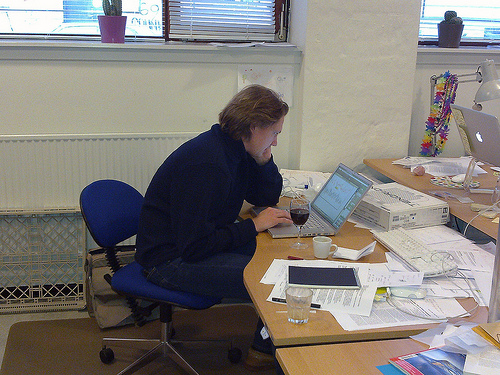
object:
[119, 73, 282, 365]
man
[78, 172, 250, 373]
chair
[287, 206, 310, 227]
wine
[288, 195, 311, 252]
glass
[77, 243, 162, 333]
bag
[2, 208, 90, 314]
baby gate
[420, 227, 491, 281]
paper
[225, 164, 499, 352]
desk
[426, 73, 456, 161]
necklace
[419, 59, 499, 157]
lamp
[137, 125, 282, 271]
sweater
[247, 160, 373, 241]
laptop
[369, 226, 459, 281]
keyboard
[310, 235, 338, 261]
cup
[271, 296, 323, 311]
pen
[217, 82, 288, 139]
hair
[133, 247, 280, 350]
jeans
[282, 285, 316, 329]
glass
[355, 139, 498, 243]
table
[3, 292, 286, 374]
floor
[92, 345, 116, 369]
wheel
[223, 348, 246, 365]
wheel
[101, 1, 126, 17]
cactus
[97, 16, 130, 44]
pot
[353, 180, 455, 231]
box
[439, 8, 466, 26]
cactus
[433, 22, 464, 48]
pot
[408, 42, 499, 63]
ledge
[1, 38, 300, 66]
ledge